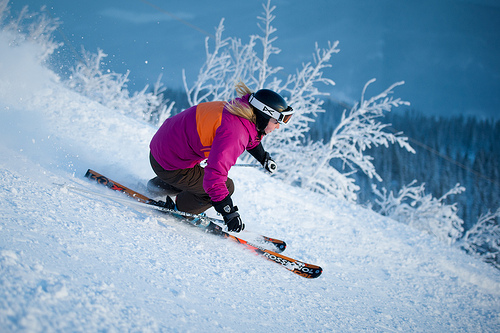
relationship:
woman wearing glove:
[146, 78, 295, 236] [260, 150, 277, 175]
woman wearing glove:
[146, 78, 295, 236] [214, 202, 245, 234]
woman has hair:
[146, 79, 295, 234] [227, 78, 256, 113]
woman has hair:
[146, 78, 295, 236] [223, 86, 276, 138]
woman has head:
[146, 78, 295, 236] [245, 82, 295, 143]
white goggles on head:
[245, 90, 294, 127] [245, 82, 295, 143]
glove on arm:
[205, 196, 263, 227] [201, 119, 251, 231]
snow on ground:
[1, 69, 499, 331] [1, 67, 499, 329]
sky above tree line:
[31, 2, 498, 112] [312, 102, 496, 155]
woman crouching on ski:
[146, 79, 295, 234] [257, 242, 325, 289]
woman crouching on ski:
[146, 79, 295, 234] [236, 222, 303, 258]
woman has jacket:
[146, 79, 295, 234] [126, 88, 281, 217]